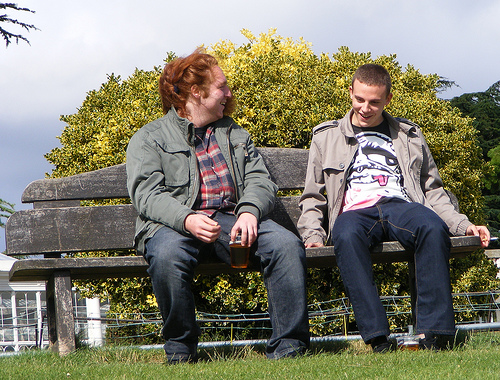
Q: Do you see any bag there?
A: No, there are no bags.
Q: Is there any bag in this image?
A: No, there are no bags.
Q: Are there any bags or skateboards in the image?
A: No, there are no bags or skateboards.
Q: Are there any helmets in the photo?
A: No, there are no helmets.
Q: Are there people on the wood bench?
A: Yes, there is a person on the bench.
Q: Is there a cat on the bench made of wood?
A: No, there is a person on the bench.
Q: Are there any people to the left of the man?
A: Yes, there is a person to the left of the man.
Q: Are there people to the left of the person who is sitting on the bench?
A: Yes, there is a person to the left of the man.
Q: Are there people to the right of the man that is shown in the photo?
A: No, the person is to the left of the man.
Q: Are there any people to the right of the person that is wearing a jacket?
A: No, the person is to the left of the man.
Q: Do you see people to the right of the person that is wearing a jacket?
A: No, the person is to the left of the man.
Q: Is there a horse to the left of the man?
A: No, there is a person to the left of the man.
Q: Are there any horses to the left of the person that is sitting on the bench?
A: No, there is a person to the left of the man.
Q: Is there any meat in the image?
A: No, there is no meat.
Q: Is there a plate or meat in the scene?
A: No, there are no meat or plates.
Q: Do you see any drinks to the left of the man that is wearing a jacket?
A: Yes, there is a drink to the left of the man.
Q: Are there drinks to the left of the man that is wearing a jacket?
A: Yes, there is a drink to the left of the man.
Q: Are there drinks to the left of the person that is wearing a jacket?
A: Yes, there is a drink to the left of the man.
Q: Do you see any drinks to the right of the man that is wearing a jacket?
A: No, the drink is to the left of the man.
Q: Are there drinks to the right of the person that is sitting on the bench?
A: No, the drink is to the left of the man.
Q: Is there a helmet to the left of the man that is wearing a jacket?
A: No, there is a drink to the left of the man.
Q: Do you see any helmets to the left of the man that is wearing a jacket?
A: No, there is a drink to the left of the man.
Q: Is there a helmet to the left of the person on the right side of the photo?
A: No, there is a drink to the left of the man.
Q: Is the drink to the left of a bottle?
A: No, the drink is to the left of a man.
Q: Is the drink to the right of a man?
A: No, the drink is to the left of a man.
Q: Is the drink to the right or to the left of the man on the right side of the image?
A: The drink is to the left of the man.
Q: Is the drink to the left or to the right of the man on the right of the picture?
A: The drink is to the left of the man.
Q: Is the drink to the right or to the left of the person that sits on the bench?
A: The drink is to the left of the man.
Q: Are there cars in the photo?
A: No, there are no cars.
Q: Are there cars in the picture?
A: No, there are no cars.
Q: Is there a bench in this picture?
A: Yes, there is a bench.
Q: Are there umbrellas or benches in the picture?
A: Yes, there is a bench.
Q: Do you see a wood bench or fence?
A: Yes, there is a wood bench.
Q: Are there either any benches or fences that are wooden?
A: Yes, the bench is wooden.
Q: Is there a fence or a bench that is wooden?
A: Yes, the bench is wooden.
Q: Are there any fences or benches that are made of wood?
A: Yes, the bench is made of wood.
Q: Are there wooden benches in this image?
A: Yes, there is a wood bench.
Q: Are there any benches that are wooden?
A: Yes, there is a bench that is wooden.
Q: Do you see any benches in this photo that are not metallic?
A: Yes, there is a wooden bench.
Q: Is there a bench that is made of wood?
A: Yes, there is a bench that is made of wood.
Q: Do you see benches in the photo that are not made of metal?
A: Yes, there is a bench that is made of wood.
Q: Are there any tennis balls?
A: No, there are no tennis balls.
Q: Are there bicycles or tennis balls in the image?
A: No, there are no tennis balls or bicycles.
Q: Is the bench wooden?
A: Yes, the bench is wooden.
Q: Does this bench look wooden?
A: Yes, the bench is wooden.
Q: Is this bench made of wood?
A: Yes, the bench is made of wood.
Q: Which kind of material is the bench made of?
A: The bench is made of wood.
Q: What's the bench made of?
A: The bench is made of wood.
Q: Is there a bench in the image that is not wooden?
A: No, there is a bench but it is wooden.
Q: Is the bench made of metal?
A: No, the bench is made of wood.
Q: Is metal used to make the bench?
A: No, the bench is made of wood.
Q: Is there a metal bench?
A: No, there is a bench but it is made of wood.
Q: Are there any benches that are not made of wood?
A: No, there is a bench but it is made of wood.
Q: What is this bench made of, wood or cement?
A: The bench is made of wood.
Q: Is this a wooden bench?
A: Yes, this is a wooden bench.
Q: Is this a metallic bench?
A: No, this is a wooden bench.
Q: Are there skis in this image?
A: No, there are no skis.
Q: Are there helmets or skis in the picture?
A: No, there are no skis or helmets.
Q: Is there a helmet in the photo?
A: No, there are no helmets.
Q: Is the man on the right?
A: Yes, the man is on the right of the image.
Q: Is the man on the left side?
A: No, the man is on the right of the image.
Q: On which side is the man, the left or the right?
A: The man is on the right of the image.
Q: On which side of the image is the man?
A: The man is on the right of the image.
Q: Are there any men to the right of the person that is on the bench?
A: Yes, there is a man to the right of the person.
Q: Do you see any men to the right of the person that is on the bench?
A: Yes, there is a man to the right of the person.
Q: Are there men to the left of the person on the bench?
A: No, the man is to the right of the person.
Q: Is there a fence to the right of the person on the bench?
A: No, there is a man to the right of the person.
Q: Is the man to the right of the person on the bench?
A: Yes, the man is to the right of the person.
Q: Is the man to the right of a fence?
A: No, the man is to the right of the person.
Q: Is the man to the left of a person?
A: No, the man is to the right of a person.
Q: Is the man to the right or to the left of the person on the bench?
A: The man is to the right of the person.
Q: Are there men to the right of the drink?
A: Yes, there is a man to the right of the drink.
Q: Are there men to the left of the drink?
A: No, the man is to the right of the drink.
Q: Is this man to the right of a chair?
A: No, the man is to the right of the drink.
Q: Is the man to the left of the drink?
A: No, the man is to the right of the drink.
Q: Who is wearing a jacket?
A: The man is wearing a jacket.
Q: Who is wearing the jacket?
A: The man is wearing a jacket.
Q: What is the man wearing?
A: The man is wearing a jacket.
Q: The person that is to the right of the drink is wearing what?
A: The man is wearing a jacket.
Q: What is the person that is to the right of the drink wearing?
A: The man is wearing a jacket.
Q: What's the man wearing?
A: The man is wearing a jacket.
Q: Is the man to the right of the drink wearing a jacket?
A: Yes, the man is wearing a jacket.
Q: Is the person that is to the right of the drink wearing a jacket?
A: Yes, the man is wearing a jacket.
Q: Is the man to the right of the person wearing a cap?
A: No, the man is wearing a jacket.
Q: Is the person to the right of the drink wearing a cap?
A: No, the man is wearing a jacket.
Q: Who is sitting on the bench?
A: The man is sitting on the bench.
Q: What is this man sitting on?
A: The man is sitting on the bench.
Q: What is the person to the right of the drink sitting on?
A: The man is sitting on the bench.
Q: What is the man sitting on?
A: The man is sitting on the bench.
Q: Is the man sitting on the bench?
A: Yes, the man is sitting on the bench.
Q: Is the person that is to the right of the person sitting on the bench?
A: Yes, the man is sitting on the bench.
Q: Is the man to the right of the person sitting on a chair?
A: No, the man is sitting on the bench.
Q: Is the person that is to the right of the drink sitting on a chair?
A: No, the man is sitting on the bench.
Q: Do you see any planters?
A: No, there are no planters.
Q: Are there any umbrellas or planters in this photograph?
A: No, there are no planters or umbrellas.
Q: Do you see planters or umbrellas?
A: No, there are no planters or umbrellas.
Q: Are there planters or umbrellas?
A: No, there are no planters or umbrellas.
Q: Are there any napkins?
A: No, there are no napkins.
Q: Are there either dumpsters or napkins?
A: No, there are no napkins or dumpsters.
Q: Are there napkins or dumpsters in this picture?
A: No, there are no napkins or dumpsters.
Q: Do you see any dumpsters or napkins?
A: No, there are no napkins or dumpsters.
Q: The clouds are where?
A: The clouds are in the sky.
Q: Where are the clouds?
A: The clouds are in the sky.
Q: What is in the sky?
A: The clouds are in the sky.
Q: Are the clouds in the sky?
A: Yes, the clouds are in the sky.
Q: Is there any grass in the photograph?
A: Yes, there is grass.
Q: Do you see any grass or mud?
A: Yes, there is grass.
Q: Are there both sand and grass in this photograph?
A: No, there is grass but no sand.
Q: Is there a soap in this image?
A: No, there are no soaps.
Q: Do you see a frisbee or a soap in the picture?
A: No, there are no soaps or frisbees.